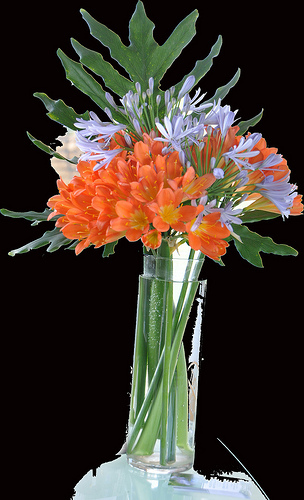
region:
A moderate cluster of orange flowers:
[54, 147, 211, 243]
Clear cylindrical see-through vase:
[134, 262, 198, 457]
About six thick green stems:
[118, 271, 198, 459]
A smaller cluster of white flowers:
[49, 83, 295, 193]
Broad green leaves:
[36, 7, 251, 140]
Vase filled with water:
[135, 275, 194, 460]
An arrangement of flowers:
[19, 73, 295, 259]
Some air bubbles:
[140, 276, 162, 353]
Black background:
[0, 29, 56, 81]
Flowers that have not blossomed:
[93, 79, 180, 133]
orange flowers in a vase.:
[44, 129, 231, 263]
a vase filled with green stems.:
[117, 238, 213, 463]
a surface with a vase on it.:
[70, 455, 254, 498]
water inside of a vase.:
[125, 298, 202, 473]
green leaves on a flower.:
[77, 1, 207, 93]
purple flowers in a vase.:
[152, 70, 244, 173]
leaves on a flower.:
[3, 239, 77, 277]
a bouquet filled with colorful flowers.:
[0, 71, 300, 264]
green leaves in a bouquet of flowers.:
[0, 2, 298, 79]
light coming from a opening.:
[159, 211, 201, 326]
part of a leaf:
[130, 4, 149, 31]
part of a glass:
[141, 468, 162, 494]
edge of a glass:
[176, 414, 209, 477]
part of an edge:
[90, 462, 115, 485]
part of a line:
[218, 436, 245, 484]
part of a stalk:
[150, 399, 177, 426]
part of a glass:
[174, 469, 187, 488]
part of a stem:
[142, 404, 162, 430]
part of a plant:
[170, 398, 192, 437]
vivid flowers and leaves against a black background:
[11, 20, 292, 296]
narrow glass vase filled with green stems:
[109, 232, 209, 473]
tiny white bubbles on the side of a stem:
[142, 272, 162, 362]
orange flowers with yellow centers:
[63, 174, 189, 231]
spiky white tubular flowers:
[223, 136, 293, 214]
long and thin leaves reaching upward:
[36, 0, 240, 109]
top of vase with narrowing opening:
[126, 220, 205, 286]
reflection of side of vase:
[176, 281, 196, 468]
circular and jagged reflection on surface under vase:
[69, 444, 263, 493]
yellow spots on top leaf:
[97, 2, 177, 75]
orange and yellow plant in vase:
[67, 154, 180, 236]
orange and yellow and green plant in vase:
[157, 145, 246, 236]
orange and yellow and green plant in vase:
[202, 128, 287, 227]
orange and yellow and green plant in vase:
[84, 87, 228, 169]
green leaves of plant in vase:
[67, 9, 217, 85]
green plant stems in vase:
[138, 271, 197, 457]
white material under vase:
[89, 473, 195, 499]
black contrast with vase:
[13, 276, 114, 446]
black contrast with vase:
[220, 283, 291, 446]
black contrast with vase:
[242, 10, 297, 102]